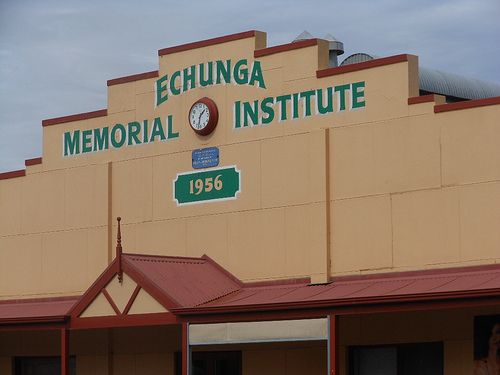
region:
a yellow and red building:
[0, 19, 497, 370]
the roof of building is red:
[3, 246, 499, 331]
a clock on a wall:
[178, 93, 223, 139]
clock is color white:
[181, 93, 224, 143]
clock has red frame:
[183, 93, 222, 141]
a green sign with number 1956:
[162, 163, 244, 209]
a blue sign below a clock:
[176, 94, 228, 171]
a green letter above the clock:
[140, 30, 283, 142]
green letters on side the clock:
[46, 79, 379, 161]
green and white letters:
[48, 50, 377, 174]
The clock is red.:
[183, 91, 225, 142]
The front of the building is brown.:
[31, 35, 487, 287]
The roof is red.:
[0, 241, 482, 316]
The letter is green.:
[150, 73, 171, 115]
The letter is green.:
[58, 130, 78, 154]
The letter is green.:
[81, 125, 93, 160]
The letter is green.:
[92, 124, 109, 154]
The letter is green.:
[125, 118, 140, 146]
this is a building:
[1, 28, 498, 368]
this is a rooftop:
[2, 213, 497, 332]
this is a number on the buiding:
[170, 163, 242, 206]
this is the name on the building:
[50, 55, 370, 157]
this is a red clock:
[185, 95, 218, 137]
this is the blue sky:
[2, 3, 498, 178]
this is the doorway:
[167, 347, 244, 371]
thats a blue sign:
[190, 146, 224, 169]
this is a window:
[345, 336, 449, 373]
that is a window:
[11, 353, 72, 373]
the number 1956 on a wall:
[169, 164, 244, 210]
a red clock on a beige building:
[180, 95, 225, 141]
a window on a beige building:
[342, 339, 449, 373]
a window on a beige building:
[3, 354, 83, 374]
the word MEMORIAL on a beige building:
[52, 112, 179, 157]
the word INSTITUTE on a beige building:
[223, 79, 368, 131]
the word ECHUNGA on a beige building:
[135, 55, 266, 110]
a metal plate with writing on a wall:
[188, 145, 221, 171]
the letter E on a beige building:
[350, 82, 365, 109]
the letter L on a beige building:
[163, 111, 181, 142]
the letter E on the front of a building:
[151, 72, 168, 107]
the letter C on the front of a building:
[169, 70, 180, 98]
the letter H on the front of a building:
[182, 65, 197, 91]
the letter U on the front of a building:
[194, 59, 217, 87]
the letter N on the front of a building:
[213, 56, 232, 85]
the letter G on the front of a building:
[228, 57, 250, 91]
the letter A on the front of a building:
[248, 58, 272, 91]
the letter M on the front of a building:
[59, 129, 81, 156]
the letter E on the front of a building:
[78, 128, 93, 155]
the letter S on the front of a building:
[258, 94, 275, 126]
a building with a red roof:
[147, 247, 437, 319]